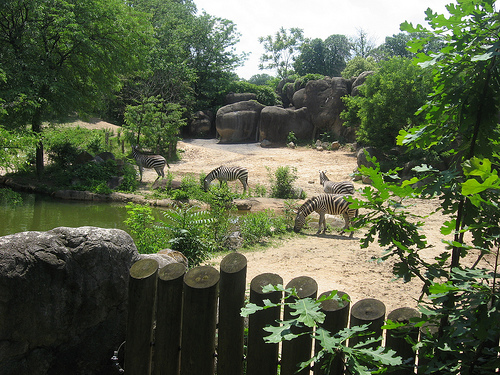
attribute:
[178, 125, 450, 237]
dirt enclosure — flat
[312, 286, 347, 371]
fence post — brown 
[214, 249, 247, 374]
post — wooden, brown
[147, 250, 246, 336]
poles — wooden 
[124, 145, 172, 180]
zebra — behind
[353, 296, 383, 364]
post — brown 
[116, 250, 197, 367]
fence posts — brown 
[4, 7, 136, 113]
tree — large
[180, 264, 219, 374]
post — brown 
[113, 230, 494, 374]
post — brown 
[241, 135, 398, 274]
zebra — standing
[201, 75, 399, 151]
rock wall — rock 